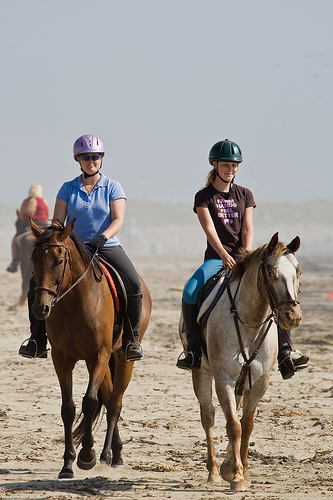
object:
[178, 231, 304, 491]
horse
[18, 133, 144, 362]
person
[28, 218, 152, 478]
horse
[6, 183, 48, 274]
person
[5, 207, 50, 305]
horse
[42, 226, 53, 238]
mane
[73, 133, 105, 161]
helmet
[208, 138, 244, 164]
helmet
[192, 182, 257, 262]
t-shirt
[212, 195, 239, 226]
letters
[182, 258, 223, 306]
pants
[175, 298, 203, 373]
boots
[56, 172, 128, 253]
shirt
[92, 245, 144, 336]
pants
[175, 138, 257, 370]
people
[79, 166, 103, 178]
strap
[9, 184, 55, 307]
away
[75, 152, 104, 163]
sunglasses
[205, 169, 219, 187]
hair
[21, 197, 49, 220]
shirt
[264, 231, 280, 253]
ear